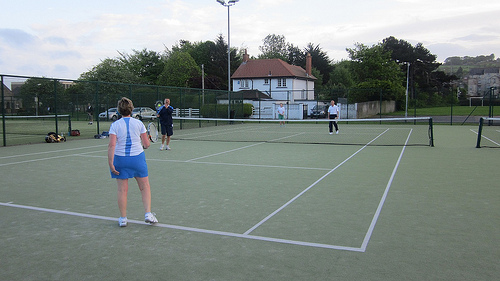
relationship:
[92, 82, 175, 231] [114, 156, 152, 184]
woman wearing shorts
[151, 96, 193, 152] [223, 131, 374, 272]
man on court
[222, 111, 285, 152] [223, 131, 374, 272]
net on court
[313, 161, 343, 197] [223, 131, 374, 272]
lines on court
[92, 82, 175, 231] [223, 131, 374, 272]
woman on court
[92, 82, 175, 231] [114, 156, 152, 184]
woman in shorts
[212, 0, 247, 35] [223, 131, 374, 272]
lamp behind court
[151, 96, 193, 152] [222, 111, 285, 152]
man near net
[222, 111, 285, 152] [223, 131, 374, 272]
net near court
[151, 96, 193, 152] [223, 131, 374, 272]
man in court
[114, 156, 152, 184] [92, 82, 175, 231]
shorts on woman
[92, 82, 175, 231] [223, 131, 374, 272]
woman in court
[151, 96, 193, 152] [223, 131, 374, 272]
man inside court